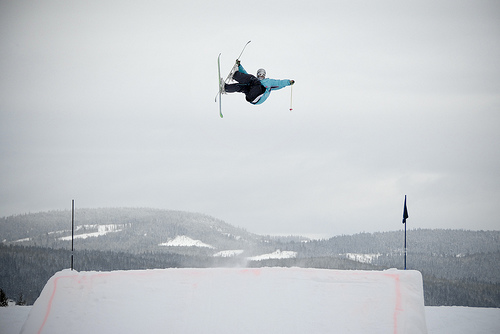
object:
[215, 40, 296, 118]
skier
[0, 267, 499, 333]
snow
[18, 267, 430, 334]
ramp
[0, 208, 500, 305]
mountains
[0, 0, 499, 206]
background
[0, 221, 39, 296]
trees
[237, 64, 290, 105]
jacket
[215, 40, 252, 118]
skis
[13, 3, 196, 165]
air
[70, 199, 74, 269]
pole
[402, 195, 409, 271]
pole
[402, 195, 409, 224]
flag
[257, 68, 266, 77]
helmet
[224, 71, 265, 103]
pants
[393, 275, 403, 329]
line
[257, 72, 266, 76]
goggles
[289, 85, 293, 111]
ski pole